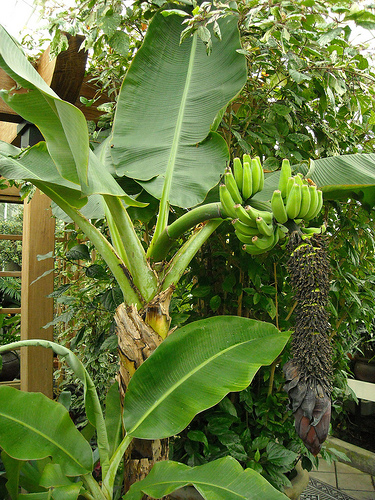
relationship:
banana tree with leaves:
[0, 21, 315, 497] [16, 0, 255, 211]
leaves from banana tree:
[16, 0, 255, 211] [0, 21, 315, 497]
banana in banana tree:
[267, 186, 291, 225] [0, 21, 315, 497]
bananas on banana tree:
[207, 147, 342, 253] [0, 21, 315, 497]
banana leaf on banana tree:
[119, 311, 297, 444] [0, 21, 315, 497]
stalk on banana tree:
[107, 201, 162, 303] [0, 21, 315, 497]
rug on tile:
[294, 471, 351, 494] [312, 452, 373, 491]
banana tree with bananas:
[0, 21, 315, 497] [207, 147, 342, 253]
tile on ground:
[312, 452, 373, 491] [275, 448, 373, 499]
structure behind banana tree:
[0, 175, 73, 401] [0, 21, 315, 497]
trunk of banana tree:
[107, 301, 180, 490] [0, 21, 315, 497]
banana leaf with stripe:
[119, 311, 297, 444] [123, 332, 259, 433]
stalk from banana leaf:
[107, 201, 162, 303] [119, 311, 297, 444]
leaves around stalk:
[16, 0, 255, 211] [107, 201, 162, 303]